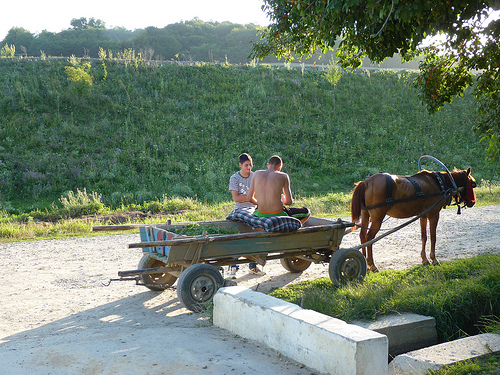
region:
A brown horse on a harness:
[347, 147, 483, 269]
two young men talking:
[224, 147, 303, 224]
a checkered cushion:
[234, 208, 303, 233]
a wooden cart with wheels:
[97, 217, 364, 306]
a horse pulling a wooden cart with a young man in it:
[93, 139, 483, 296]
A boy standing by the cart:
[225, 152, 265, 283]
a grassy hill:
[115, 72, 217, 182]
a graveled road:
[20, 255, 113, 345]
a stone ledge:
[215, 286, 388, 373]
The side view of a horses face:
[447, 158, 483, 217]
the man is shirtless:
[254, 169, 297, 215]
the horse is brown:
[351, 163, 476, 258]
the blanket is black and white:
[237, 215, 298, 230]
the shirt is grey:
[229, 176, 254, 217]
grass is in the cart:
[155, 217, 349, 266]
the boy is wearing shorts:
[248, 155, 300, 225]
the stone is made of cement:
[217, 280, 388, 365]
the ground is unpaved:
[32, 252, 112, 335]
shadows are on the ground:
[62, 295, 168, 367]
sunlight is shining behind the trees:
[346, 30, 498, 82]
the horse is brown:
[373, 190, 485, 328]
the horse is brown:
[395, 58, 422, 219]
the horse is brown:
[368, 118, 408, 312]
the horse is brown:
[371, 142, 416, 284]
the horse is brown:
[352, 125, 432, 360]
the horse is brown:
[378, 141, 445, 338]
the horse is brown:
[385, 65, 435, 310]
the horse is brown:
[382, 101, 442, 332]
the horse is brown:
[406, 125, 491, 320]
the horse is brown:
[367, 157, 430, 248]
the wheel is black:
[177, 283, 189, 299]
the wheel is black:
[185, 275, 196, 287]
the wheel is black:
[179, 266, 194, 286]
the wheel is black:
[182, 257, 193, 279]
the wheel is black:
[176, 269, 190, 296]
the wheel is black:
[180, 297, 191, 314]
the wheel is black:
[183, 285, 193, 294]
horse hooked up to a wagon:
[55, 148, 497, 328]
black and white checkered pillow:
[220, 198, 307, 240]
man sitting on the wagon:
[249, 146, 330, 251]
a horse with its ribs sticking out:
[362, 155, 477, 240]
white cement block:
[180, 275, 405, 372]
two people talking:
[212, 125, 306, 244]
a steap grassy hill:
[8, 41, 497, 224]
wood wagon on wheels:
[75, 205, 380, 312]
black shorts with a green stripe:
[245, 202, 312, 224]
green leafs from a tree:
[252, 5, 498, 155]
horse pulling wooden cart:
[86, 146, 481, 317]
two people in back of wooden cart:
[87, 150, 369, 313]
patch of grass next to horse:
[270, 245, 499, 337]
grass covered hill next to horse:
[2, 52, 498, 223]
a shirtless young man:
[248, 153, 308, 223]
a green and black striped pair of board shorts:
[252, 206, 309, 220]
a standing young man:
[227, 152, 263, 277]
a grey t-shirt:
[229, 169, 253, 209]